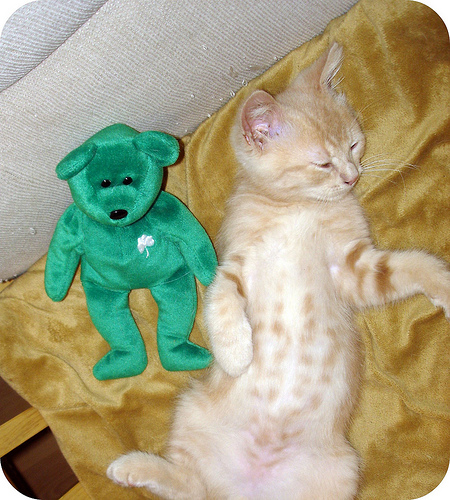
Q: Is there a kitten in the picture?
A: Yes, there is a kitten.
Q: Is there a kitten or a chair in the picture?
A: Yes, there is a kitten.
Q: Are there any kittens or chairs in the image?
A: Yes, there is a kitten.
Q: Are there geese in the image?
A: No, there are no geese.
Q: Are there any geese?
A: No, there are no geese.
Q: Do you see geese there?
A: No, there are no geese.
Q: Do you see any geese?
A: No, there are no geese.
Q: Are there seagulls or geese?
A: No, there are no geese or seagulls.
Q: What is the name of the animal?
A: The animal is a kitten.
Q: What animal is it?
A: The animal is a kitten.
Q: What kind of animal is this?
A: This is a kitten.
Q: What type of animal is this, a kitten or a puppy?
A: This is a kitten.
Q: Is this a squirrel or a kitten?
A: This is a kitten.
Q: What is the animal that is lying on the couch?
A: The animal is a kitten.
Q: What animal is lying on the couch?
A: The animal is a kitten.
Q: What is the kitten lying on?
A: The kitten is lying on the couch.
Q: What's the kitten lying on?
A: The kitten is lying on the couch.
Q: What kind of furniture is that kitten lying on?
A: The kitten is lying on the couch.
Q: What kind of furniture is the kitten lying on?
A: The kitten is lying on the couch.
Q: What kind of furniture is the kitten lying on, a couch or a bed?
A: The kitten is lying on a couch.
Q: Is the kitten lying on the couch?
A: Yes, the kitten is lying on the couch.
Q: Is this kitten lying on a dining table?
A: No, the kitten is lying on the couch.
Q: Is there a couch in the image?
A: Yes, there is a couch.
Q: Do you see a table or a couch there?
A: Yes, there is a couch.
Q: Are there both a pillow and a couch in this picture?
A: No, there is a couch but no pillows.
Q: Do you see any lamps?
A: No, there are no lamps.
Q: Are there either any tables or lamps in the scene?
A: No, there are no lamps or tables.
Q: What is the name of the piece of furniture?
A: The piece of furniture is a couch.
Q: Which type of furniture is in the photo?
A: The furniture is a couch.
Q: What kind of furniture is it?
A: The piece of furniture is a couch.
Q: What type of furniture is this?
A: This is a couch.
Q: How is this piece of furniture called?
A: This is a couch.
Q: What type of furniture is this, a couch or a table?
A: This is a couch.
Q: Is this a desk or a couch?
A: This is a couch.